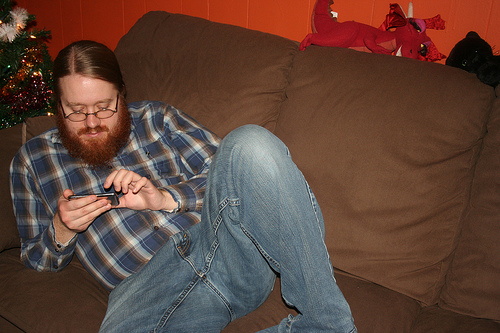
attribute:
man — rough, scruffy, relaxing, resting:
[35, 39, 320, 307]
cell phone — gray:
[69, 187, 127, 223]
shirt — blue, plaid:
[47, 144, 86, 191]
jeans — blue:
[241, 145, 288, 216]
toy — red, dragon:
[311, 2, 430, 55]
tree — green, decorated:
[7, 13, 40, 96]